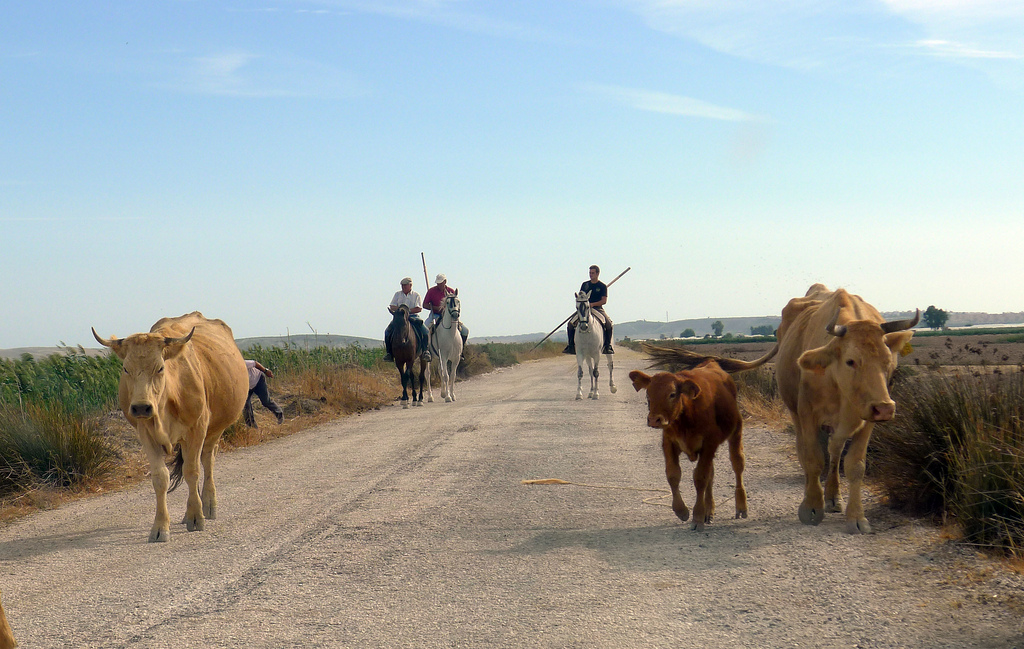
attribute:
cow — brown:
[80, 302, 270, 538]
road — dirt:
[11, 291, 1005, 645]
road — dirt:
[36, 256, 982, 643]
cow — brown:
[617, 351, 782, 530]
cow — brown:
[769, 258, 906, 514]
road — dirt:
[769, 258, 906, 514]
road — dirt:
[539, 251, 622, 391]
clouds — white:
[144, 70, 227, 143]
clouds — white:
[394, 32, 496, 128]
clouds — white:
[658, 84, 756, 154]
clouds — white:
[829, 176, 925, 244]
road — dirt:
[0, 343, 1024, 644]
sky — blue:
[1, 3, 1019, 349]